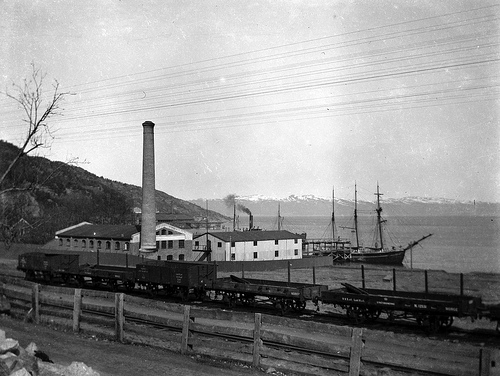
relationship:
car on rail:
[16, 249, 78, 283] [0, 267, 27, 280]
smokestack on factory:
[138, 120, 159, 260] [53, 220, 306, 268]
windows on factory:
[227, 239, 235, 249] [185, 222, 312, 272]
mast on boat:
[344, 179, 381, 250] [319, 186, 434, 267]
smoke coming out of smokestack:
[222, 194, 252, 216] [240, 217, 262, 231]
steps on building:
[187, 238, 215, 260] [191, 224, 308, 269]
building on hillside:
[191, 224, 306, 261] [8, 148, 195, 247]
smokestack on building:
[139, 120, 157, 260] [54, 213, 198, 269]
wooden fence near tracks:
[0, 274, 497, 374] [13, 267, 480, 340]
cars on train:
[216, 272, 489, 329] [13, 243, 499, 350]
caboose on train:
[17, 243, 222, 300] [13, 243, 499, 350]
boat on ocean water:
[307, 179, 440, 279] [245, 218, 498, 275]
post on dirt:
[30, 283, 42, 328] [13, 328, 161, 374]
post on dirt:
[68, 284, 81, 337] [13, 328, 161, 374]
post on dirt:
[111, 293, 128, 340] [13, 328, 161, 374]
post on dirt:
[179, 304, 195, 359] [13, 328, 161, 374]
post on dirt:
[250, 314, 262, 374] [13, 328, 161, 374]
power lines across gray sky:
[17, 34, 498, 124] [171, 78, 474, 180]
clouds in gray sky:
[251, 117, 446, 177] [171, 78, 474, 180]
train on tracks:
[16, 248, 498, 343] [0, 262, 497, 352]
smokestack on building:
[139, 120, 157, 260] [141, 119, 158, 251]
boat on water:
[350, 180, 435, 265] [222, 213, 499, 273]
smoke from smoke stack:
[222, 194, 249, 216] [244, 216, 256, 229]